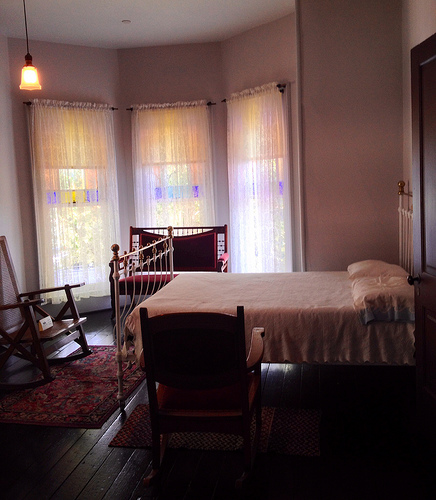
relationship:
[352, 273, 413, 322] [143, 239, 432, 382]
pillow on bed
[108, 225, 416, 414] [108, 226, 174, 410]
bed on frame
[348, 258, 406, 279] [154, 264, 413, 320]
pillow on bed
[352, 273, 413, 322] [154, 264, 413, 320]
pillow on bed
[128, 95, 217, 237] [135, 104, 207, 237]
curtain in front of window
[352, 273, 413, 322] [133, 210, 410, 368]
pillow on bed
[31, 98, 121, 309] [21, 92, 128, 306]
curtain with curtains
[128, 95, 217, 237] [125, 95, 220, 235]
curtain with curtains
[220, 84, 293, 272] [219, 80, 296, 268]
curtain with curtains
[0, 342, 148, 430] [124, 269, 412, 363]
carpet at foot of bed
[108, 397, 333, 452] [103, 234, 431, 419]
carpet on side of bed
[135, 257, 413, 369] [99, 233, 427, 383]
sheet on bed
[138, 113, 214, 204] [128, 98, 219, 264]
stained glass through curtains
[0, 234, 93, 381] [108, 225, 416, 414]
chair by bed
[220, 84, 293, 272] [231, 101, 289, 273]
curtain in front of window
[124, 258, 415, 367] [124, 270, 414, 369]
bed with sheets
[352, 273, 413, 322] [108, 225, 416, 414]
pillow on bed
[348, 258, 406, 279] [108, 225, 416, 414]
pillow on bed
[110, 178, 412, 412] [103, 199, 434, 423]
frame on bed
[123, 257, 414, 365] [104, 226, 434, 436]
blanket on bed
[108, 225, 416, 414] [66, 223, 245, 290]
bed with cradle